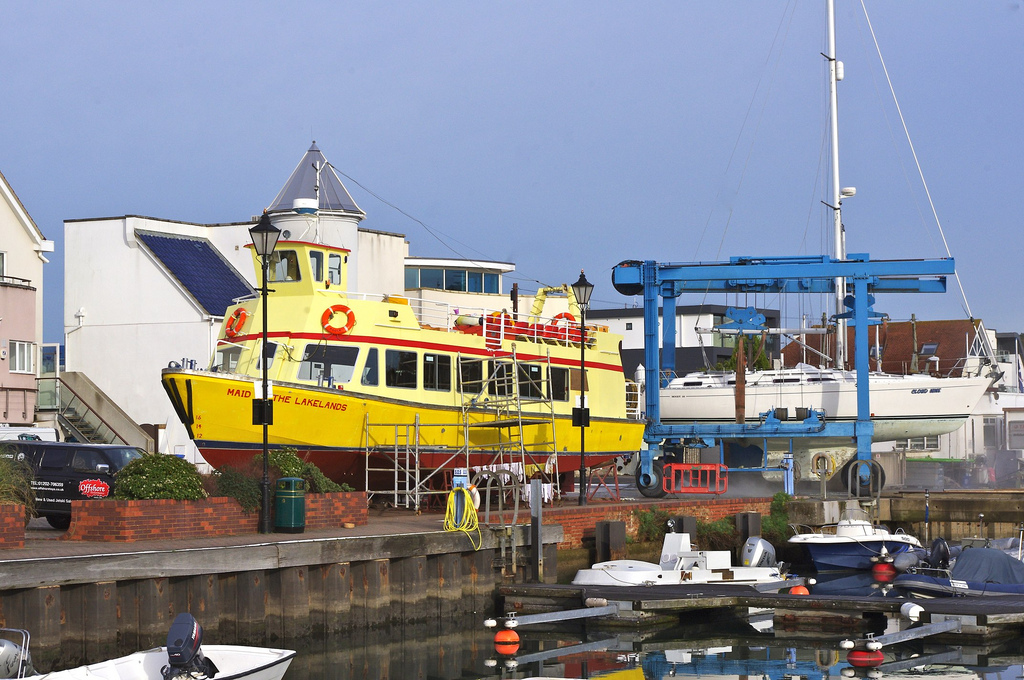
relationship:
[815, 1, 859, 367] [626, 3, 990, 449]
mast mounted on boat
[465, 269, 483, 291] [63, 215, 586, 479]
window adorning building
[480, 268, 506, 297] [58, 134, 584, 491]
window adorning building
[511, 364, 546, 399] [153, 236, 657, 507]
window on boat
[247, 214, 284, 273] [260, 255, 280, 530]
lamp on post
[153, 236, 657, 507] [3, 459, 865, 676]
boat on land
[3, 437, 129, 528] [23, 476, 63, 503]
van with text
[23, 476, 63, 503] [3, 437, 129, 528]
text on van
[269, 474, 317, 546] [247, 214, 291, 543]
bin next to post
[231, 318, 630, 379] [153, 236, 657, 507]
stripe on boat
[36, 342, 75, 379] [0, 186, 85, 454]
window on building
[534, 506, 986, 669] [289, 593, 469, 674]
boats in water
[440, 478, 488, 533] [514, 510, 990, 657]
rope next to boats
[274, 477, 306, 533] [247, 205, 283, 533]
bin next to post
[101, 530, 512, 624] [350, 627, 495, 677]
wall next to water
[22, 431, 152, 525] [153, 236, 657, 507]
van parked in front of boat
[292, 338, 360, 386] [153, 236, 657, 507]
window on boat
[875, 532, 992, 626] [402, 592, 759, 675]
boat in water